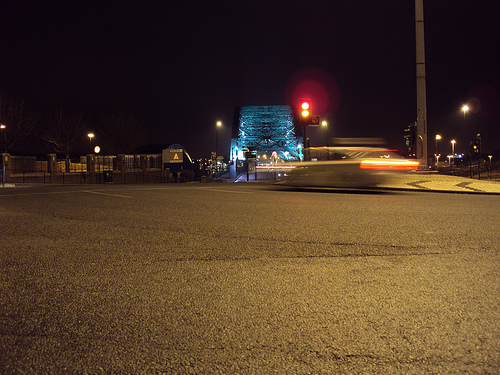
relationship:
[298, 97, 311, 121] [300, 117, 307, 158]
signal light on oile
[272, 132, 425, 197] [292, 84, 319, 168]
car zooming through signal light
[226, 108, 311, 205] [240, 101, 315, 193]
stone wall beside bridge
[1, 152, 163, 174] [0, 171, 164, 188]
fence on top of wall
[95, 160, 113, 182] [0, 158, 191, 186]
receptacle next to wall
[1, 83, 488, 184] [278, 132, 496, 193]
lamps beside bridge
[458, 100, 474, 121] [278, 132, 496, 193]
lamps beside bridge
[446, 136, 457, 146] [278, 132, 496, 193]
lamps beside bridge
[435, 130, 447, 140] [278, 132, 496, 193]
lamps beside bridge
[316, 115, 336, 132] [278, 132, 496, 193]
lamps beside bridge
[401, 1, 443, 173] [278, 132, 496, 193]
pole beside bridge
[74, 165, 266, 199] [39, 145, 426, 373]
lines on ground